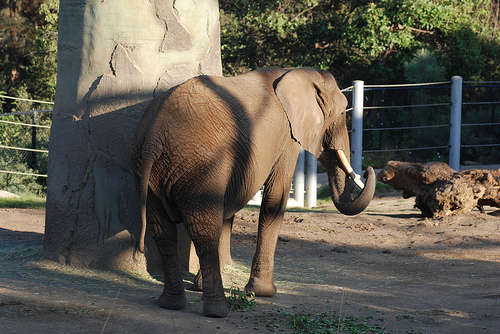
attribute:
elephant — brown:
[129, 63, 269, 245]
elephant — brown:
[128, 65, 377, 317]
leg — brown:
[178, 152, 232, 316]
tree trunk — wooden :
[375, 157, 498, 224]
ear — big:
[273, 64, 320, 159]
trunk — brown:
[323, 143, 380, 225]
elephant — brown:
[139, 41, 381, 263]